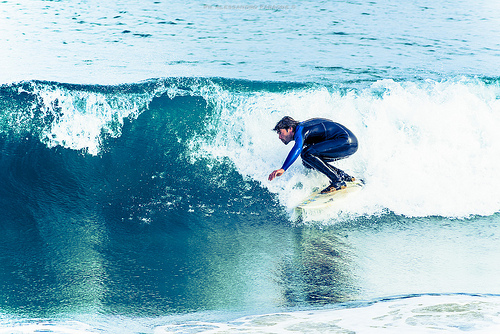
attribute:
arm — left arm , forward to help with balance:
[284, 128, 305, 170]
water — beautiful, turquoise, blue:
[0, 1, 497, 331]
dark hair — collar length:
[273, 114, 301, 131]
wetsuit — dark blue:
[248, 116, 363, 185]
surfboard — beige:
[304, 190, 386, 220]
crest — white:
[24, 82, 497, 227]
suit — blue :
[257, 104, 362, 204]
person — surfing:
[229, 110, 449, 240]